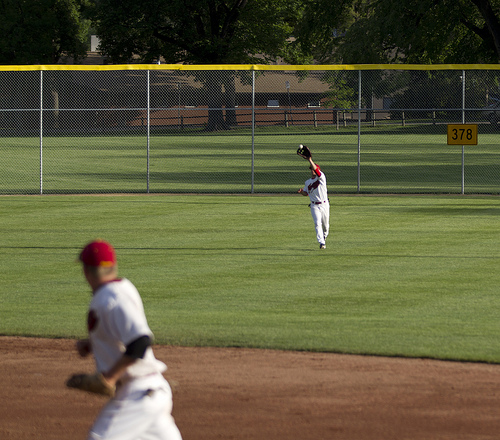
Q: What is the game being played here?
A: Baseball.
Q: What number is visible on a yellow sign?
A: 378.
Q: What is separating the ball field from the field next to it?
A: A tall, chain link fence.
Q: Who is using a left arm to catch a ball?
A: A baseball player.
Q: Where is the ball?
A: In the air.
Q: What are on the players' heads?
A: Baseball caps.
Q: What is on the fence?
A: A distance sign.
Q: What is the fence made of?
A: Chain link.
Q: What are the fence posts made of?
A: Metal.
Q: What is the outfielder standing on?
A: Grass.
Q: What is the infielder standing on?
A: Dirt.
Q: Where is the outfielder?
A: On the grass.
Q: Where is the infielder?
A: On the dirt.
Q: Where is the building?
A: Behind the fence.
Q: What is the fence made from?
A: Metal.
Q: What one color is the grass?
A: Green.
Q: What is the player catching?
A: A ball.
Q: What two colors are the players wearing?
A: Red and white.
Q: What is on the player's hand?
A: A baseball mitt.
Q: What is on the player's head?
A: A hat.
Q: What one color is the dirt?
A: Brown.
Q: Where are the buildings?
A: On the other side of the fence.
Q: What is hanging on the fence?
A: A sign.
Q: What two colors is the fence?
A: Silver and yellow.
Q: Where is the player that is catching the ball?
A: In the outfield.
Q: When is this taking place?
A: Daytime.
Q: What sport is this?
A: Baseball.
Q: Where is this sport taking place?
A: Baseball field.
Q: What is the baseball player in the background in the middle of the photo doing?
A: Catching ball.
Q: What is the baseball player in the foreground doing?
A: Running.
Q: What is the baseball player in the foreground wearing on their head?
A: Hat.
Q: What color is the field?
A: Brown and green.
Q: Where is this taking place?
A: A baseball field.